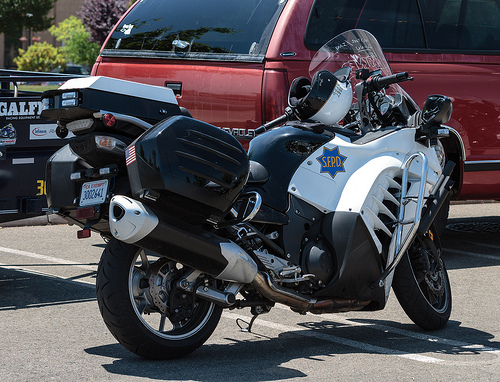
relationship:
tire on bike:
[377, 199, 465, 341] [41, 28, 467, 361]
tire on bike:
[92, 226, 230, 361] [27, 21, 472, 361]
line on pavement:
[2, 247, 494, 372] [0, 211, 498, 378]